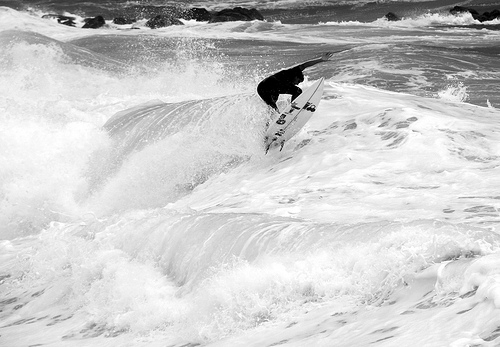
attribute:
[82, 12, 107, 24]
rock — black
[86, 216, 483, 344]
wave — large, foamy 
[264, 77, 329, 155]
surfboard — white 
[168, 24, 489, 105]
spot — calm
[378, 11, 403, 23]
rock — sharp, pointy, black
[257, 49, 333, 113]
person — single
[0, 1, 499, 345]
water — splash , little , white , foamy  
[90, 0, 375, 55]
rocks — pictured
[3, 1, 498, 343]
photo — black and white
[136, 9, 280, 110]
water — clear, dark